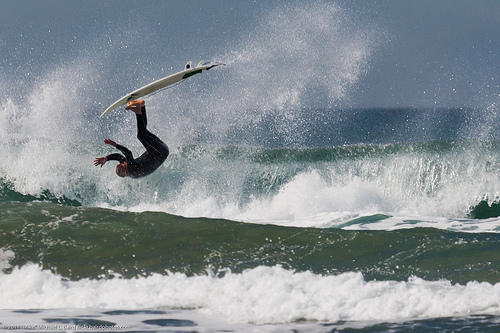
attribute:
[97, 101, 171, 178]
man — falling, upside down, wet, surfing, bent, surfer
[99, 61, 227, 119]
surfboard — flying, white, upside down, short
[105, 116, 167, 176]
wetsuit — black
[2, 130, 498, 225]
wave — breaking, splashing, large, spraying, crashing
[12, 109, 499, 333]
water — dirty, wavey, white, ocean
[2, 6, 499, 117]
sky — blue